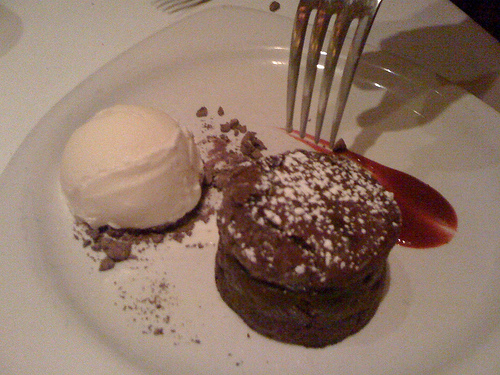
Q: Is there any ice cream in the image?
A: Yes, there is ice cream.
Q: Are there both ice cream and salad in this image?
A: No, there is ice cream but no salad.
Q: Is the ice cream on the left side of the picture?
A: Yes, the ice cream is on the left of the image.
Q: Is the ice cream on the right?
A: No, the ice cream is on the left of the image.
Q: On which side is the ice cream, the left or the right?
A: The ice cream is on the left of the image.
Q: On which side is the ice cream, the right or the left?
A: The ice cream is on the left of the image.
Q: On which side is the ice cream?
A: The ice cream is on the left of the image.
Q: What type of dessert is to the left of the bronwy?
A: The dessert is ice cream.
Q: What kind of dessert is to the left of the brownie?
A: The dessert is ice cream.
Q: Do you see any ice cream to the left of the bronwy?
A: Yes, there is ice cream to the left of the bronwy.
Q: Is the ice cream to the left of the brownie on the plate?
A: Yes, the ice cream is to the left of the brownie.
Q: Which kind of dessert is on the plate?
A: The dessert is ice cream.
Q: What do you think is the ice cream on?
A: The ice cream is on the plate.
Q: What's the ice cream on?
A: The ice cream is on the plate.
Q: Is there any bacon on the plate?
A: No, there is ice cream on the plate.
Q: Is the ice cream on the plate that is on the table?
A: Yes, the ice cream is on the plate.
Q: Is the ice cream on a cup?
A: No, the ice cream is on the plate.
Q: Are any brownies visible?
A: Yes, there is a brownie.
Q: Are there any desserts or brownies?
A: Yes, there is a brownie.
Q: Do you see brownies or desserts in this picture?
A: Yes, there is a brownie.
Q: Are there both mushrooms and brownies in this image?
A: No, there is a brownie but no mushrooms.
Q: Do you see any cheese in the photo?
A: No, there is no cheese.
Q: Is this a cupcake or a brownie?
A: This is a brownie.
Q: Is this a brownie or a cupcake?
A: This is a brownie.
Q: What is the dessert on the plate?
A: The dessert is a brownie.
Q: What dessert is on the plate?
A: The dessert is a brownie.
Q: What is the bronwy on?
A: The bronwy is on the plate.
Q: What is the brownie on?
A: The bronwy is on the plate.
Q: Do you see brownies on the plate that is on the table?
A: Yes, there is a brownie on the plate.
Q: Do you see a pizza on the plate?
A: No, there is a brownie on the plate.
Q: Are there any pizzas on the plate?
A: No, there is a brownie on the plate.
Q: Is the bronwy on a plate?
A: Yes, the bronwy is on a plate.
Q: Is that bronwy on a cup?
A: No, the bronwy is on a plate.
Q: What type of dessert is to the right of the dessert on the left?
A: The dessert is a brownie.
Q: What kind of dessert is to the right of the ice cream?
A: The dessert is a brownie.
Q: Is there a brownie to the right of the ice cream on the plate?
A: Yes, there is a brownie to the right of the ice cream.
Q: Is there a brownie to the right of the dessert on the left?
A: Yes, there is a brownie to the right of the ice cream.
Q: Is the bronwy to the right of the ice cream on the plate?
A: Yes, the bronwy is to the right of the ice cream.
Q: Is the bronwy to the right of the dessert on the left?
A: Yes, the bronwy is to the right of the ice cream.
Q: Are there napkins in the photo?
A: No, there are no napkins.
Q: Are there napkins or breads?
A: No, there are no napkins or breads.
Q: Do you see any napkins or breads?
A: No, there are no napkins or breads.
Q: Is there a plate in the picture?
A: Yes, there is a plate.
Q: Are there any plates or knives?
A: Yes, there is a plate.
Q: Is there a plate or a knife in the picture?
A: Yes, there is a plate.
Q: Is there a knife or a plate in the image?
A: Yes, there is a plate.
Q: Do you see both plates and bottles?
A: No, there is a plate but no bottles.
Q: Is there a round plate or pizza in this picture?
A: Yes, there is a round plate.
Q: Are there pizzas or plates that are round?
A: Yes, the plate is round.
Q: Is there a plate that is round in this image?
A: Yes, there is a round plate.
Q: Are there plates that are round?
A: Yes, there is a plate that is round.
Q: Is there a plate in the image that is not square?
A: Yes, there is a round plate.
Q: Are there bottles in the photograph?
A: No, there are no bottles.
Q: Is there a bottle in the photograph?
A: No, there are no bottles.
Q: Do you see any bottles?
A: No, there are no bottles.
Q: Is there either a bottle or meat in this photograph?
A: No, there are no bottles or meat.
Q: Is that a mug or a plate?
A: That is a plate.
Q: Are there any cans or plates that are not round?
A: No, there is a plate but it is round.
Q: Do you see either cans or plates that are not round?
A: No, there is a plate but it is round.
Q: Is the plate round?
A: Yes, the plate is round.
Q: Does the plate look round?
A: Yes, the plate is round.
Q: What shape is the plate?
A: The plate is round.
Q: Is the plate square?
A: No, the plate is round.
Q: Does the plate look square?
A: No, the plate is round.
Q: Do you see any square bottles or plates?
A: No, there is a plate but it is round.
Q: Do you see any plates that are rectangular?
A: No, there is a plate but it is round.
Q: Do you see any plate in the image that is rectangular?
A: No, there is a plate but it is round.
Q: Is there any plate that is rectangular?
A: No, there is a plate but it is round.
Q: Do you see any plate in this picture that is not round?
A: No, there is a plate but it is round.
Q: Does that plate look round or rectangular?
A: The plate is round.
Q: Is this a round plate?
A: Yes, this is a round plate.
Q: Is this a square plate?
A: No, this is a round plate.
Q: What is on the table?
A: The plate is on the table.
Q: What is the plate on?
A: The plate is on the table.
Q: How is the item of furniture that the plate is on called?
A: The piece of furniture is a table.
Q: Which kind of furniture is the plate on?
A: The plate is on the table.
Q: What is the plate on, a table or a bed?
A: The plate is on a table.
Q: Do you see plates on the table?
A: Yes, there is a plate on the table.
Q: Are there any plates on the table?
A: Yes, there is a plate on the table.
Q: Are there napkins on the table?
A: No, there is a plate on the table.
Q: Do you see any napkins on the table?
A: No, there is a plate on the table.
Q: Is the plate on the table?
A: Yes, the plate is on the table.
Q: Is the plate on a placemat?
A: No, the plate is on the table.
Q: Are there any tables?
A: Yes, there is a table.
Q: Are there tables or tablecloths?
A: Yes, there is a table.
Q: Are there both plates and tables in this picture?
A: Yes, there are both a table and a plate.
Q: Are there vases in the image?
A: No, there are no vases.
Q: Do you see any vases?
A: No, there are no vases.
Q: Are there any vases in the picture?
A: No, there are no vases.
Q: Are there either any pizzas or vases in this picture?
A: No, there are no vases or pizzas.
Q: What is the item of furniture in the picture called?
A: The piece of furniture is a table.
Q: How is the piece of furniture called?
A: The piece of furniture is a table.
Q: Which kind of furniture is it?
A: The piece of furniture is a table.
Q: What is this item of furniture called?
A: This is a table.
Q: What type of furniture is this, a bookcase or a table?
A: This is a table.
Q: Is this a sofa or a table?
A: This is a table.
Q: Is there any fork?
A: Yes, there is a fork.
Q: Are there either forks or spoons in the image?
A: Yes, there is a fork.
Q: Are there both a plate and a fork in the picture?
A: Yes, there are both a fork and a plate.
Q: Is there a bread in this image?
A: No, there is no breads.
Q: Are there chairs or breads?
A: No, there are no breads or chairs.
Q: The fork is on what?
A: The fork is on the plate.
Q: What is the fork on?
A: The fork is on the plate.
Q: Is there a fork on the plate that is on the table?
A: Yes, there is a fork on the plate.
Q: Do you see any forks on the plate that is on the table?
A: Yes, there is a fork on the plate.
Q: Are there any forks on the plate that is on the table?
A: Yes, there is a fork on the plate.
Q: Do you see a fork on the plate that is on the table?
A: Yes, there is a fork on the plate.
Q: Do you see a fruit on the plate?
A: No, there is a fork on the plate.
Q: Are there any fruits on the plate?
A: No, there is a fork on the plate.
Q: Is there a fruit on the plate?
A: No, there is a fork on the plate.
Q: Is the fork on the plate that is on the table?
A: Yes, the fork is on the plate.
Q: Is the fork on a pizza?
A: No, the fork is on the plate.